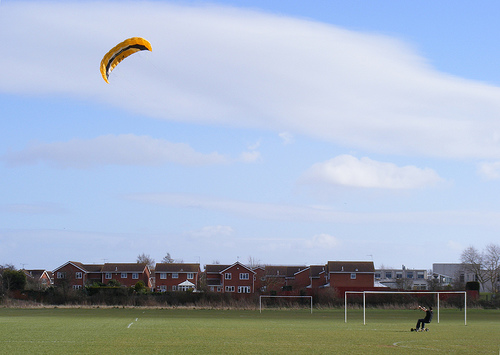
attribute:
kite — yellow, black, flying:
[100, 36, 154, 83]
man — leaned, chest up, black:
[410, 303, 436, 333]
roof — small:
[326, 260, 377, 275]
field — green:
[1, 306, 498, 354]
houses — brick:
[0, 261, 499, 301]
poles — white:
[343, 289, 470, 329]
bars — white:
[344, 290, 469, 327]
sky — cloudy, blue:
[0, 1, 500, 271]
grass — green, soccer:
[1, 308, 498, 354]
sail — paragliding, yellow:
[98, 34, 158, 85]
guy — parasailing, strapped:
[409, 303, 437, 335]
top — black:
[423, 311, 434, 321]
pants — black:
[414, 318, 430, 329]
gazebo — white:
[177, 279, 196, 292]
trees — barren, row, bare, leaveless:
[0, 264, 211, 307]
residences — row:
[20, 260, 499, 307]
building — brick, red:
[16, 260, 378, 295]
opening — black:
[467, 281, 480, 291]